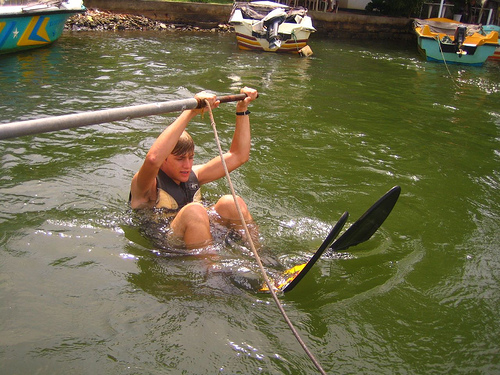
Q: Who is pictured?
A: A man.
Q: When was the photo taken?
A: Daylight hours.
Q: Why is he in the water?
A: Water sking.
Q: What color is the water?
A: Green.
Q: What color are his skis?
A: Black and yellow.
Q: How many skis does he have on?
A: Two.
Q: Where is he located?
A: In the water.